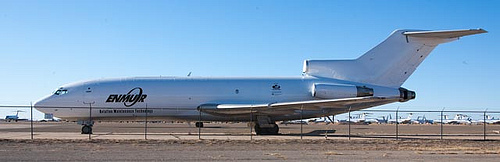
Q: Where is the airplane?
A: On the runway.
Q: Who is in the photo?
A: Nobody.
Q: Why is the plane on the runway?
A: It is going to take off.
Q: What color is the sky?
A: Blue.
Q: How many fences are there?
A: One.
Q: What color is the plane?
A: White.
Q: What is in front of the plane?
A: A fence.